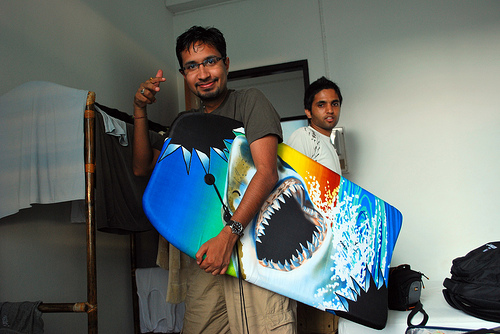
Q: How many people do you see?
A: 2.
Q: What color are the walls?
A: White.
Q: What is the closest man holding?
A: Boogie board.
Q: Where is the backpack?
A: On the table to the right.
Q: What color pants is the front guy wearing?
A: Tan.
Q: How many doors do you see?
A: 1.